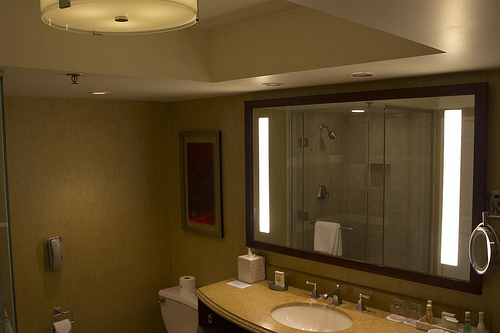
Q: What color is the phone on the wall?
A: White.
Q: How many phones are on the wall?
A: One.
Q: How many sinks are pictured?
A: One.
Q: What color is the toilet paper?
A: White.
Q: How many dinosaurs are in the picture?
A: Zero.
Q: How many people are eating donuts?
A: Zero.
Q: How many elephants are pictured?
A: Zero.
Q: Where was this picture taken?
A: In a bathroom.